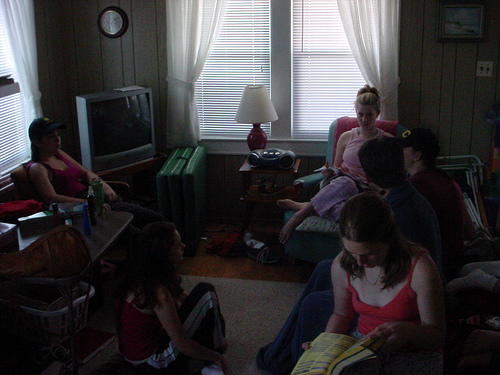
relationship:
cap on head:
[23, 113, 62, 147] [25, 113, 65, 166]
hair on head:
[122, 208, 180, 304] [123, 210, 195, 310]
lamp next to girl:
[229, 80, 282, 152] [270, 75, 400, 242]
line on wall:
[414, 17, 425, 120] [419, 27, 482, 136]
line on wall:
[440, 51, 442, 134] [419, 27, 482, 136]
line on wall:
[468, 93, 478, 158] [419, 27, 482, 136]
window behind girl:
[184, 0, 372, 142] [278, 83, 393, 237]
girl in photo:
[300, 191, 443, 375] [1, 1, 498, 373]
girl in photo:
[101, 214, 241, 370] [1, 1, 498, 373]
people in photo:
[355, 138, 475, 284] [1, 1, 498, 373]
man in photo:
[394, 123, 479, 283] [1, 1, 498, 373]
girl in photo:
[270, 75, 400, 242] [1, 1, 498, 373]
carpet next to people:
[189, 275, 297, 371] [17, 81, 482, 346]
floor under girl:
[176, 229, 311, 281] [23, 115, 161, 247]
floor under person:
[176, 229, 311, 281] [299, 190, 438, 373]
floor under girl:
[176, 229, 311, 281] [270, 75, 400, 242]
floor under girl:
[176, 229, 311, 281] [300, 191, 443, 375]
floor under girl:
[176, 229, 311, 281] [101, 214, 241, 370]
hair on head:
[130, 208, 180, 298] [121, 217, 201, 285]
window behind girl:
[184, 0, 372, 142] [270, 75, 400, 242]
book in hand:
[288, 330, 390, 373] [368, 320, 405, 346]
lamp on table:
[229, 80, 282, 152] [237, 152, 307, 245]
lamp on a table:
[229, 80, 282, 152] [243, 155, 301, 200]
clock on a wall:
[97, 8, 126, 36] [59, 5, 165, 76]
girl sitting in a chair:
[23, 115, 161, 247] [11, 165, 141, 226]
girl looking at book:
[300, 191, 443, 375] [296, 324, 390, 374]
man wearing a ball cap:
[394, 123, 479, 283] [396, 124, 441, 158]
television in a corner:
[54, 80, 159, 180] [31, 9, 184, 226]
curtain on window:
[164, 0, 224, 145] [162, 3, 400, 150]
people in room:
[11, 35, 476, 362] [7, 35, 498, 373]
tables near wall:
[157, 142, 213, 262] [40, 0, 492, 232]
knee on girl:
[190, 279, 222, 323] [109, 221, 230, 365]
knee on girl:
[330, 175, 359, 201] [277, 90, 397, 245]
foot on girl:
[265, 207, 312, 259] [267, 73, 408, 258]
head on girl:
[331, 193, 404, 274] [298, 191, 445, 374]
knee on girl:
[190, 279, 222, 323] [93, 211, 248, 373]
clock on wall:
[97, 8, 126, 36] [61, 4, 172, 186]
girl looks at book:
[300, 191, 443, 375] [288, 330, 390, 373]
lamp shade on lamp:
[230, 81, 279, 124] [233, 84, 279, 149]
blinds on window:
[194, 0, 359, 137] [162, 3, 400, 150]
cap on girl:
[23, 110, 71, 147] [101, 214, 241, 370]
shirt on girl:
[340, 120, 388, 182] [270, 75, 400, 242]